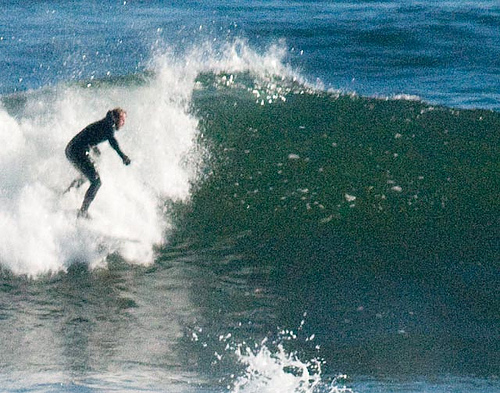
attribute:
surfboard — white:
[71, 210, 141, 245]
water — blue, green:
[0, 3, 497, 386]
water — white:
[0, 54, 329, 287]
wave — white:
[0, 54, 298, 284]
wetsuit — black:
[63, 109, 123, 207]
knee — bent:
[88, 174, 103, 190]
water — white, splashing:
[212, 326, 353, 392]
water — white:
[145, 25, 322, 99]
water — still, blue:
[0, 3, 499, 111]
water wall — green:
[0, 63, 499, 273]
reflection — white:
[2, 250, 211, 392]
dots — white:
[197, 94, 422, 222]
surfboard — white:
[73, 218, 145, 248]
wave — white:
[4, 39, 301, 278]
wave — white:
[0, 32, 320, 288]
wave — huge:
[10, 64, 388, 266]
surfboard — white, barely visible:
[46, 194, 144, 248]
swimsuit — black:
[61, 119, 133, 219]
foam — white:
[182, 306, 354, 391]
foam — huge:
[1, 30, 301, 290]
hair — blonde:
[108, 107, 128, 120]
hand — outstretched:
[122, 155, 132, 167]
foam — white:
[2, 21, 319, 282]